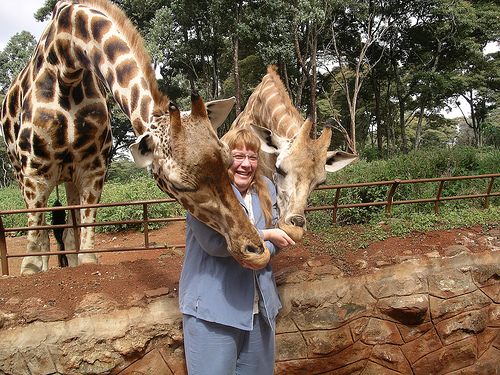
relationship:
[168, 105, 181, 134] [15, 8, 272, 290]
horn on giraffe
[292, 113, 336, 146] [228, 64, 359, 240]
horns on giraffe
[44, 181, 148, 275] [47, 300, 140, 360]
rail on wall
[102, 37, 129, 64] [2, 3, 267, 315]
spot on giraffe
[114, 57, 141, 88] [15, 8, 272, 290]
spot on giraffe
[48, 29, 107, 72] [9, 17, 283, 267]
spot on giraffe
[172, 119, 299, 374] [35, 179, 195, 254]
woman standing in front of wall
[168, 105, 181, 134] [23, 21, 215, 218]
horn on giraffe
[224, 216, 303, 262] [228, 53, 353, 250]
hand under giraffe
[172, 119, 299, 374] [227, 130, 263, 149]
woman has bangs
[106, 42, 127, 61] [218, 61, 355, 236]
spot on giraffe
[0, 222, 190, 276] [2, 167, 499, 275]
path behind railing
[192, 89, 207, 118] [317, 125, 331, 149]
horn to right of horn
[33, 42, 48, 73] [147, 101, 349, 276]
spot on giraffe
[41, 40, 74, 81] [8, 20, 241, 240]
spot on giraffe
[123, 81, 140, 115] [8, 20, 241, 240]
spot on giraffe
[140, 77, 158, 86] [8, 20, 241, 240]
spot on giraffe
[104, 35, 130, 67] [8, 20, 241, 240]
spot on giraffe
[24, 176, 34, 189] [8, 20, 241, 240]
spot on giraffe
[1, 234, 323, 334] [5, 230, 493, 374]
dirt on wall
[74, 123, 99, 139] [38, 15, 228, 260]
spot on giraffe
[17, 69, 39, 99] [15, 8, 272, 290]
spot on giraffe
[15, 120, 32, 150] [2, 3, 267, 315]
spot on giraffe